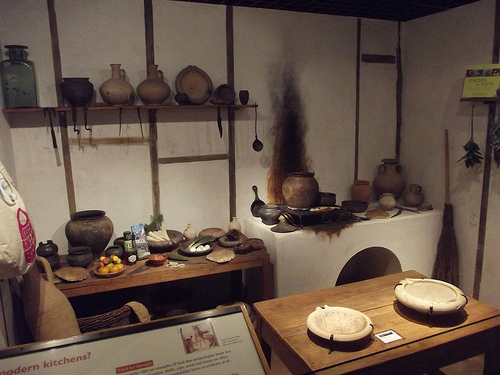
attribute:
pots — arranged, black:
[41, 43, 270, 103]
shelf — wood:
[19, 105, 258, 121]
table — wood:
[226, 276, 485, 349]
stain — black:
[272, 94, 312, 169]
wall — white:
[253, 17, 352, 158]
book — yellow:
[455, 65, 499, 103]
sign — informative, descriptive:
[1, 296, 245, 365]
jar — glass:
[5, 39, 46, 116]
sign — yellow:
[463, 57, 499, 101]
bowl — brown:
[63, 205, 119, 249]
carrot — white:
[149, 204, 168, 238]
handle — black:
[247, 183, 260, 199]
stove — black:
[257, 202, 370, 235]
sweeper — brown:
[444, 148, 475, 287]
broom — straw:
[429, 211, 473, 294]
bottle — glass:
[3, 47, 44, 106]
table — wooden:
[21, 241, 257, 336]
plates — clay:
[308, 264, 459, 337]